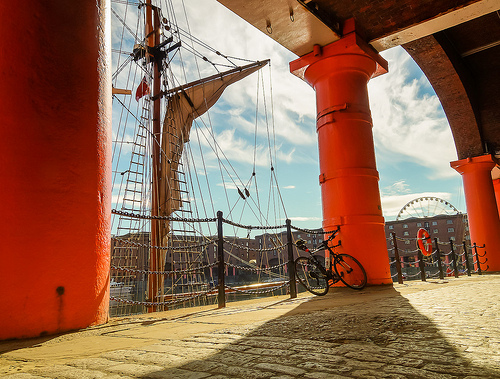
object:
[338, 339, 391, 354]
brick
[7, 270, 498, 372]
walk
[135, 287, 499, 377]
shadow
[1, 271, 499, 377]
ground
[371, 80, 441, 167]
whitecloud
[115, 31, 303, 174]
whitecloud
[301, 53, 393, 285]
pillar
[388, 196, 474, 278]
ferris wheel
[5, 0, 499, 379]
building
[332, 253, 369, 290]
tire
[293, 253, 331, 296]
tire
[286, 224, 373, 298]
bike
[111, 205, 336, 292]
fence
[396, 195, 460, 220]
ferris wheel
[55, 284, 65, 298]
spot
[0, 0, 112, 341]
pillar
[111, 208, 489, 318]
rope fence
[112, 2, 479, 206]
cloud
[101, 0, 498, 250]
sky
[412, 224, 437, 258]
life vest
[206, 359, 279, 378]
bricks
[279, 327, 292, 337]
cobblestone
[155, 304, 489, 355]
surface